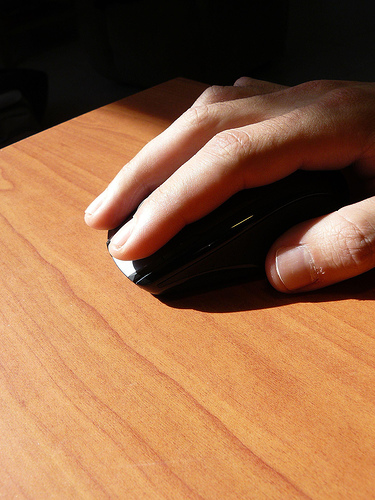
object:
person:
[82, 77, 374, 295]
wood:
[0, 74, 374, 499]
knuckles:
[188, 104, 227, 139]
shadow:
[153, 216, 375, 313]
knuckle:
[210, 123, 247, 175]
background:
[0, 0, 375, 146]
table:
[0, 79, 375, 499]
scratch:
[116, 454, 195, 473]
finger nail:
[84, 196, 103, 214]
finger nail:
[110, 216, 136, 247]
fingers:
[265, 195, 375, 297]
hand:
[82, 77, 374, 295]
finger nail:
[276, 244, 317, 289]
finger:
[107, 86, 345, 263]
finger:
[84, 79, 327, 229]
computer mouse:
[104, 170, 341, 296]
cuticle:
[312, 261, 326, 279]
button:
[106, 215, 212, 283]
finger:
[190, 76, 280, 113]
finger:
[231, 76, 293, 92]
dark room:
[0, 0, 375, 155]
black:
[175, 234, 224, 273]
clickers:
[106, 217, 171, 261]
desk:
[0, 61, 375, 500]